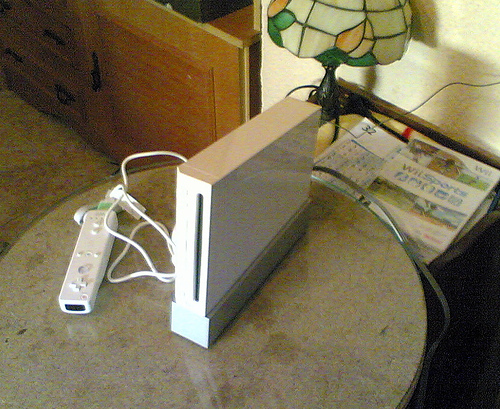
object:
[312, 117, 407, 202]
book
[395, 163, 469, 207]
text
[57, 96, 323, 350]
game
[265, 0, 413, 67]
lamp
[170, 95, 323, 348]
console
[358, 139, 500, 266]
book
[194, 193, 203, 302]
disk slit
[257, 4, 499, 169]
wall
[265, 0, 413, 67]
lamp shade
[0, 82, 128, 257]
carpet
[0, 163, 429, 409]
table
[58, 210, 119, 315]
controller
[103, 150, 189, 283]
cord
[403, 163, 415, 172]
print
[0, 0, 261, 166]
cabinets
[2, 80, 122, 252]
floor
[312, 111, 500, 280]
chair